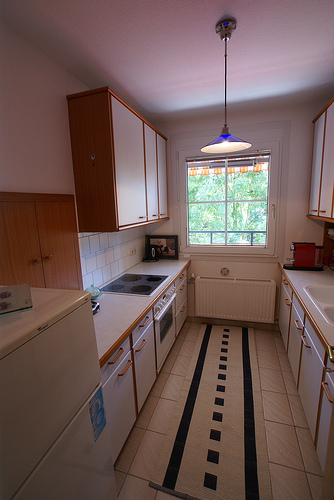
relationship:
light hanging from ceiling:
[190, 12, 257, 155] [0, 0, 333, 129]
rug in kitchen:
[148, 321, 272, 498] [0, 0, 332, 498]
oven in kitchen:
[151, 280, 179, 365] [0, 0, 332, 498]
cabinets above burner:
[62, 76, 186, 251] [108, 284, 125, 290]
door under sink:
[289, 304, 303, 381] [306, 281, 332, 319]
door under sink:
[299, 330, 323, 443] [306, 281, 332, 319]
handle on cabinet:
[133, 336, 148, 354] [125, 313, 173, 412]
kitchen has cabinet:
[0, 0, 332, 498] [1, 191, 83, 291]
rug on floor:
[148, 321, 272, 498] [180, 318, 314, 494]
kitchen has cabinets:
[0, 0, 332, 498] [58, 84, 173, 228]